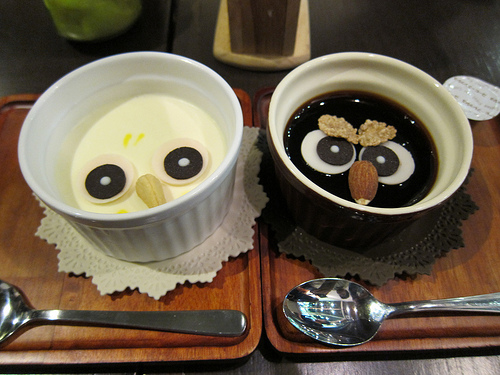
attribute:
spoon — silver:
[281, 272, 498, 352]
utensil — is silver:
[281, 275, 498, 349]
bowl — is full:
[267, 37, 458, 239]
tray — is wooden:
[251, 90, 498, 352]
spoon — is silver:
[272, 269, 484, 329]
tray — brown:
[0, 87, 262, 364]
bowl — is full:
[311, 101, 433, 176]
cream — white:
[47, 90, 231, 220]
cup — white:
[12, 45, 247, 268]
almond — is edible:
[346, 157, 377, 207]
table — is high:
[0, 2, 493, 373]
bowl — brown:
[265, 45, 476, 249]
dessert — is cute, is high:
[287, 63, 442, 213]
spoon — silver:
[281, 278, 499, 347]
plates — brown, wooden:
[0, 92, 261, 365]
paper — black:
[255, 140, 497, 289]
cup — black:
[255, 41, 479, 248]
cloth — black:
[250, 40, 484, 286]